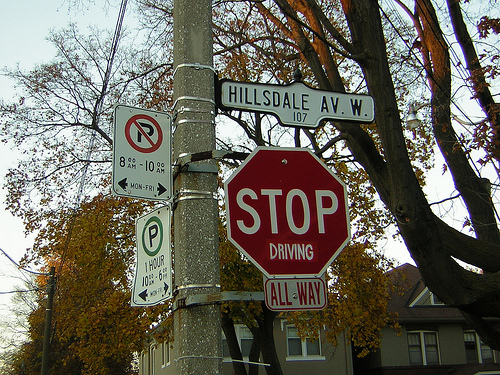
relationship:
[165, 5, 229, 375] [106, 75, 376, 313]
pole has signs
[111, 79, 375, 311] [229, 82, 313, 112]
signs says hillsdale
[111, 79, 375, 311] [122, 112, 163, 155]
signs says no-parking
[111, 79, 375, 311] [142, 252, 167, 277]
signs says 1-hour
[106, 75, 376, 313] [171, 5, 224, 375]
signs have pole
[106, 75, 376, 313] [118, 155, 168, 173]
signs have numbers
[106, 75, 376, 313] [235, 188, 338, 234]
signs have letter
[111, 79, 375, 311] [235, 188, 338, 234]
signs says letter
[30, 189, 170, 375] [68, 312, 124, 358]
tree has part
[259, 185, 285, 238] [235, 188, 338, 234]
letter has letter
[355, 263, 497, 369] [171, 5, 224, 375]
house behind pole